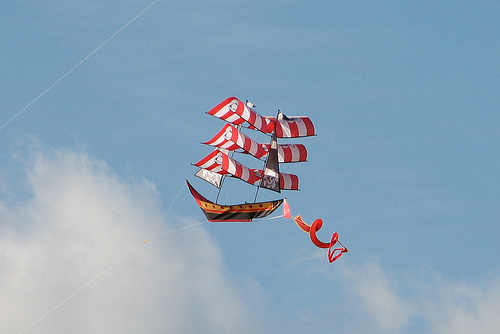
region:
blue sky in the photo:
[362, 75, 448, 152]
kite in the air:
[177, 93, 346, 250]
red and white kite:
[167, 92, 341, 237]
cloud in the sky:
[32, 156, 164, 266]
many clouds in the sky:
[57, 188, 448, 309]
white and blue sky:
[68, 75, 198, 233]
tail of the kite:
[280, 205, 357, 274]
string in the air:
[51, 28, 170, 96]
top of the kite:
[218, 90, 343, 135]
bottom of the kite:
[198, 188, 269, 230]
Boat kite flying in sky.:
[175, 89, 360, 264]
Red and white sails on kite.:
[189, 93, 318, 193]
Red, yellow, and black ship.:
[181, 182, 282, 234]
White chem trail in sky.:
[17, 0, 161, 140]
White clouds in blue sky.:
[12, 251, 496, 328]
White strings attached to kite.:
[5, 189, 196, 330]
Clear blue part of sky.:
[260, 4, 492, 105]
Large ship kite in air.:
[181, 93, 369, 267]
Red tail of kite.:
[290, 213, 346, 265]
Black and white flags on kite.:
[242, 97, 294, 124]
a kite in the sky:
[178, 90, 348, 267]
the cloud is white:
[26, 149, 125, 251]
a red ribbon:
[301, 215, 343, 260]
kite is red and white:
[188, 90, 332, 185]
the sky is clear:
[356, 45, 498, 182]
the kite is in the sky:
[147, 88, 383, 266]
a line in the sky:
[33, 52, 75, 86]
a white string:
[96, 252, 143, 280]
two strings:
[156, 185, 208, 245]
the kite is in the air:
[183, 89, 341, 267]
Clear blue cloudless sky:
[281, 28, 471, 86]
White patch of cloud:
[44, 195, 122, 254]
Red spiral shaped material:
[301, 218, 350, 266]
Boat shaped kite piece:
[185, 192, 300, 225]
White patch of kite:
[196, 171, 225, 187]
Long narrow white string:
[33, 83, 60, 102]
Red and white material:
[213, 121, 251, 149]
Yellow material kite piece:
[203, 201, 238, 211]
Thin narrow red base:
[210, 218, 254, 220]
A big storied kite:
[176, 87, 353, 268]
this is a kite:
[165, 61, 371, 258]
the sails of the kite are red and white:
[187, 89, 333, 181]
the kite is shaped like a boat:
[165, 173, 302, 233]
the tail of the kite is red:
[288, 208, 378, 286]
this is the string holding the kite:
[33, 33, 185, 130]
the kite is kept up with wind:
[53, 13, 477, 309]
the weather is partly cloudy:
[48, 48, 450, 324]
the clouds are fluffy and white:
[13, 198, 148, 330]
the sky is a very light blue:
[220, 25, 431, 128]